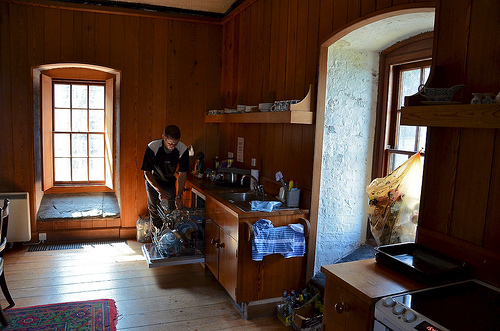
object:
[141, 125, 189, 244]
man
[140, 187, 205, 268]
dishwasher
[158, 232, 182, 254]
dishes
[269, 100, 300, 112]
cup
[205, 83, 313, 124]
cupboard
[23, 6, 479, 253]
kitchen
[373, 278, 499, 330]
stove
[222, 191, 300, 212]
sink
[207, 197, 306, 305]
cabinet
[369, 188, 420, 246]
trash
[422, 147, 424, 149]
nail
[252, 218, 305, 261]
towel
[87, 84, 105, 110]
window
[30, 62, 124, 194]
arch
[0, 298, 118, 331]
rug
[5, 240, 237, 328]
floor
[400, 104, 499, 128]
shelf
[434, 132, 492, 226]
wall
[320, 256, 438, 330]
cabinet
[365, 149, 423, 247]
bag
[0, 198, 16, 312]
chair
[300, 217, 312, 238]
rack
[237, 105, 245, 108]
dishes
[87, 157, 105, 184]
window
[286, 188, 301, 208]
container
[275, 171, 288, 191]
utensils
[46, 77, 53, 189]
wood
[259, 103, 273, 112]
bowls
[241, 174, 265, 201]
faucet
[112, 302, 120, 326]
fringe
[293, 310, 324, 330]
box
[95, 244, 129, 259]
sunlight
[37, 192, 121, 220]
spot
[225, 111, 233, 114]
plates